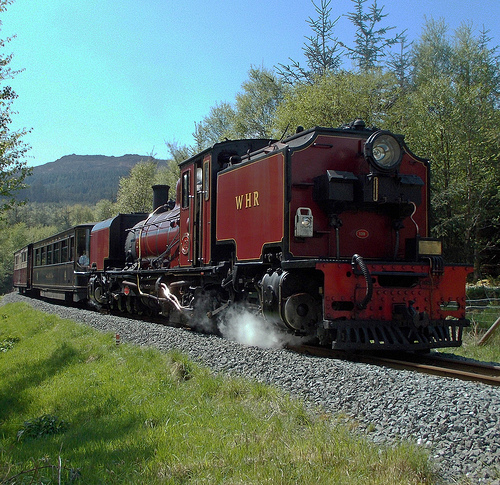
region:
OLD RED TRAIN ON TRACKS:
[75, 116, 483, 337]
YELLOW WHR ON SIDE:
[232, 180, 282, 217]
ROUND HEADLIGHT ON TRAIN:
[372, 131, 418, 170]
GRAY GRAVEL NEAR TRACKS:
[327, 346, 410, 422]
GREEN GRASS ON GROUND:
[113, 384, 255, 451]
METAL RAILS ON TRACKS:
[373, 346, 498, 376]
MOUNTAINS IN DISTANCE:
[61, 144, 150, 198]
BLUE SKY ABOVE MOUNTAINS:
[52, 44, 151, 110]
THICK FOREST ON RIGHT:
[314, 41, 494, 123]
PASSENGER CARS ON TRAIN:
[13, 214, 96, 280]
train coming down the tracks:
[11, 120, 468, 370]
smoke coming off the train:
[212, 302, 274, 349]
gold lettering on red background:
[230, 186, 262, 213]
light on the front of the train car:
[371, 136, 399, 167]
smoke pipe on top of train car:
[148, 178, 170, 212]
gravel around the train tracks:
[2, 285, 499, 483]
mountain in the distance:
[5, 143, 166, 213]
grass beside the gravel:
[3, 302, 399, 484]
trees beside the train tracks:
[71, 20, 496, 301]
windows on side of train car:
[27, 237, 69, 267]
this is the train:
[96, 103, 431, 343]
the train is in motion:
[174, 114, 432, 329]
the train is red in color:
[257, 158, 288, 191]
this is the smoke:
[223, 307, 272, 344]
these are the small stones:
[390, 374, 452, 436]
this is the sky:
[46, 3, 185, 117]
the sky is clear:
[83, 15, 194, 87]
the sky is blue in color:
[88, 4, 240, 73]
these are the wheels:
[112, 292, 153, 317]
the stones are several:
[368, 373, 440, 433]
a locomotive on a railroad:
[6, 111, 498, 383]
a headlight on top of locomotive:
[360, 120, 405, 174]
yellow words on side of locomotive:
[227, 180, 267, 217]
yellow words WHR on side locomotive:
[231, 188, 264, 215]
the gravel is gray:
[335, 355, 480, 438]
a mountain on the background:
[0, 145, 180, 215]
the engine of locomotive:
[100, 162, 186, 307]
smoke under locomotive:
[198, 292, 319, 349]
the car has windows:
[26, 221, 78, 296]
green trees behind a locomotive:
[118, 0, 496, 361]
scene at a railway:
[116, 179, 472, 379]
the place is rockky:
[346, 351, 479, 453]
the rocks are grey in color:
[365, 369, 477, 475]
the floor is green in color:
[196, 395, 324, 483]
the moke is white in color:
[223, 295, 278, 362]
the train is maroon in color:
[233, 170, 398, 229]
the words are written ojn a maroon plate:
[233, 185, 264, 222]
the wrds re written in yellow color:
[227, 181, 256, 214]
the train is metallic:
[266, 264, 327, 321]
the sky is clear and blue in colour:
[107, 57, 205, 104]